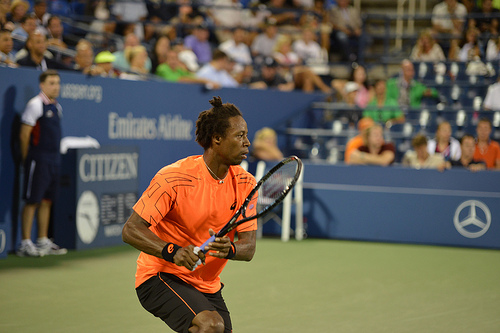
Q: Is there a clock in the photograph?
A: Yes, there is a clock.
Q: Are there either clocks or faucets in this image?
A: Yes, there is a clock.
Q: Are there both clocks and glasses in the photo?
A: No, there is a clock but no glasses.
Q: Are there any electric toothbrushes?
A: No, there are no electric toothbrushes.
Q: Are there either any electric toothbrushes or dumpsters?
A: No, there are no electric toothbrushes or dumpsters.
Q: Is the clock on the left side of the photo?
A: Yes, the clock is on the left of the image.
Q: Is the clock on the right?
A: No, the clock is on the left of the image.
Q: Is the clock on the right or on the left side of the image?
A: The clock is on the left of the image.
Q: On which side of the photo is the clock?
A: The clock is on the left of the image.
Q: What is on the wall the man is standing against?
A: The clock is on the wall.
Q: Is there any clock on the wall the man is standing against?
A: Yes, there is a clock on the wall.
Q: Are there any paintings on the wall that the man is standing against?
A: No, there is a clock on the wall.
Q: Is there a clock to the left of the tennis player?
A: Yes, there is a clock to the left of the player.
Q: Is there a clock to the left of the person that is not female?
A: Yes, there is a clock to the left of the player.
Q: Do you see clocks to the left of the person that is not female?
A: Yes, there is a clock to the left of the player.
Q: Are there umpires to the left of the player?
A: No, there is a clock to the left of the player.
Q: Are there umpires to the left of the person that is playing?
A: No, there is a clock to the left of the player.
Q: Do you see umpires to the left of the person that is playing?
A: No, there is a clock to the left of the player.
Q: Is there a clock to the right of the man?
A: Yes, there is a clock to the right of the man.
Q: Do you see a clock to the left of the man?
A: No, the clock is to the right of the man.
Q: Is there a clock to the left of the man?
A: No, the clock is to the right of the man.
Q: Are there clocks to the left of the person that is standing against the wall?
A: No, the clock is to the right of the man.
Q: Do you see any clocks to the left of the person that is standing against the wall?
A: No, the clock is to the right of the man.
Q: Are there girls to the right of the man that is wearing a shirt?
A: No, there is a clock to the right of the man.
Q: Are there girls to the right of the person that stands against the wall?
A: No, there is a clock to the right of the man.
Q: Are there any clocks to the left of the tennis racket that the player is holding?
A: Yes, there is a clock to the left of the racket.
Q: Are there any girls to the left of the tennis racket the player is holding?
A: No, there is a clock to the left of the tennis racket.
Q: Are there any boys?
A: No, there are no boys.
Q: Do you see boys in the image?
A: No, there are no boys.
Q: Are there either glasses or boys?
A: No, there are no boys or glasses.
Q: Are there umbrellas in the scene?
A: No, there are no umbrellas.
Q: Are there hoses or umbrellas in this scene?
A: No, there are no umbrellas or hoses.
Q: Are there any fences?
A: No, there are no fences.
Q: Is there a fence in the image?
A: No, there are no fences.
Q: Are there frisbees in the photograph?
A: No, there are no frisbees.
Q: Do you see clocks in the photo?
A: Yes, there is a clock.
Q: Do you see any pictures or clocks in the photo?
A: Yes, there is a clock.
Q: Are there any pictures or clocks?
A: Yes, there is a clock.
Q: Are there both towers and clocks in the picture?
A: No, there is a clock but no towers.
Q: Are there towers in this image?
A: No, there are no towers.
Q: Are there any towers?
A: No, there are no towers.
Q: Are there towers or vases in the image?
A: No, there are no towers or vases.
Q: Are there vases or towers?
A: No, there are no towers or vases.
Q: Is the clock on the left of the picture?
A: Yes, the clock is on the left of the image.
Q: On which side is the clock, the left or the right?
A: The clock is on the left of the image.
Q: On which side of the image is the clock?
A: The clock is on the left of the image.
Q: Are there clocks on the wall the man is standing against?
A: Yes, there is a clock on the wall.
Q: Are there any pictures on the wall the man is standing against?
A: No, there is a clock on the wall.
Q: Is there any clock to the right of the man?
A: Yes, there is a clock to the right of the man.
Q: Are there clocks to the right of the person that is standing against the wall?
A: Yes, there is a clock to the right of the man.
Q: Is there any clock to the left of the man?
A: No, the clock is to the right of the man.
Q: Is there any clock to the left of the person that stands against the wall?
A: No, the clock is to the right of the man.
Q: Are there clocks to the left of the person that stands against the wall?
A: No, the clock is to the right of the man.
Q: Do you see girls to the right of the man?
A: No, there is a clock to the right of the man.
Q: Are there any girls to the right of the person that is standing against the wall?
A: No, there is a clock to the right of the man.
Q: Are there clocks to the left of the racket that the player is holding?
A: Yes, there is a clock to the left of the tennis racket.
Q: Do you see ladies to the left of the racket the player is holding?
A: No, there is a clock to the left of the racket.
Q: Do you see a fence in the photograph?
A: No, there are no fences.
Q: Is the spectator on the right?
A: Yes, the spectator is on the right of the image.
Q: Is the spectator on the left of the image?
A: No, the spectator is on the right of the image.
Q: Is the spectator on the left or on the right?
A: The spectator is on the right of the image.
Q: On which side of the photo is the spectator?
A: The spectator is on the right of the image.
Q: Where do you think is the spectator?
A: The spectator is at the match.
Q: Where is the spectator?
A: The spectator is at the match.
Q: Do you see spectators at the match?
A: Yes, there is a spectator at the match.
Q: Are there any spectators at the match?
A: Yes, there is a spectator at the match.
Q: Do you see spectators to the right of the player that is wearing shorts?
A: Yes, there is a spectator to the right of the player.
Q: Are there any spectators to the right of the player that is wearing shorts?
A: Yes, there is a spectator to the right of the player.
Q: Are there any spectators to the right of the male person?
A: Yes, there is a spectator to the right of the player.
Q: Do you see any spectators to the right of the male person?
A: Yes, there is a spectator to the right of the player.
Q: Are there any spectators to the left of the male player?
A: No, the spectator is to the right of the player.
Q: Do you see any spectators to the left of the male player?
A: No, the spectator is to the right of the player.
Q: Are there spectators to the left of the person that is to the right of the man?
A: No, the spectator is to the right of the player.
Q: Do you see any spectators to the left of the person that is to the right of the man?
A: No, the spectator is to the right of the player.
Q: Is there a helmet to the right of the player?
A: No, there is a spectator to the right of the player.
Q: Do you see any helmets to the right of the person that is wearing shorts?
A: No, there is a spectator to the right of the player.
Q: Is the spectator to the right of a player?
A: Yes, the spectator is to the right of a player.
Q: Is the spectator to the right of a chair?
A: No, the spectator is to the right of a player.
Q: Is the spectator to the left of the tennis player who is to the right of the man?
A: No, the spectator is to the right of the player.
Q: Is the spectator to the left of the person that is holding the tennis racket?
A: No, the spectator is to the right of the player.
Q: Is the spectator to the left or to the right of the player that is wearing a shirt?
A: The spectator is to the right of the player.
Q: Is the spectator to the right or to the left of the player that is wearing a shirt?
A: The spectator is to the right of the player.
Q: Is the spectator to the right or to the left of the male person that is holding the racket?
A: The spectator is to the right of the player.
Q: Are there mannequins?
A: No, there are no mannequins.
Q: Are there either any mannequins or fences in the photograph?
A: No, there are no mannequins or fences.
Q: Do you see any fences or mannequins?
A: No, there are no mannequins or fences.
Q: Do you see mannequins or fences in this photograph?
A: No, there are no mannequins or fences.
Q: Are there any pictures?
A: No, there are no pictures.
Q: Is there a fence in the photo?
A: No, there are no fences.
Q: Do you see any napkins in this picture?
A: No, there are no napkins.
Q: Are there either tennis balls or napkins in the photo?
A: No, there are no napkins or tennis balls.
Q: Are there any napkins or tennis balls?
A: No, there are no napkins or tennis balls.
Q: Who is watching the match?
A: The audience is watching the match.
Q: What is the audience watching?
A: The audience is watching the match.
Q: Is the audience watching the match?
A: Yes, the audience is watching the match.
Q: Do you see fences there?
A: No, there are no fences.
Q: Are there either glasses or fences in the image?
A: No, there are no fences or glasses.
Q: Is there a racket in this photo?
A: Yes, there is a racket.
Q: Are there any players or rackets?
A: Yes, there is a racket.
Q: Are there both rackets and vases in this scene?
A: No, there is a racket but no vases.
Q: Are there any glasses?
A: No, there are no glasses.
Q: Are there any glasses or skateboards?
A: No, there are no glasses or skateboards.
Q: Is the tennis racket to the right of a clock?
A: Yes, the tennis racket is to the right of a clock.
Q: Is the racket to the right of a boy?
A: No, the racket is to the right of a clock.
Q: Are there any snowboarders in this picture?
A: No, there are no snowboarders.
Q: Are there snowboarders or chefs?
A: No, there are no snowboarders or chefs.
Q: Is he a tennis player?
A: Yes, this is a tennis player.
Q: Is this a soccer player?
A: No, this is a tennis player.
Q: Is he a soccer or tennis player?
A: This is a tennis player.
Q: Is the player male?
A: Yes, the player is male.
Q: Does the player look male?
A: Yes, the player is male.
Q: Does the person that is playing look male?
A: Yes, the player is male.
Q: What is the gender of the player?
A: The player is male.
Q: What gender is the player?
A: The player is male.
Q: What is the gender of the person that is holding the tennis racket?
A: The player is male.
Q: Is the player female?
A: No, the player is male.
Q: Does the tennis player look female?
A: No, the player is male.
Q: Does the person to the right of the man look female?
A: No, the player is male.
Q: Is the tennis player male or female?
A: The player is male.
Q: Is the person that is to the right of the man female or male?
A: The player is male.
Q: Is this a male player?
A: Yes, this is a male player.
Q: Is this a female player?
A: No, this is a male player.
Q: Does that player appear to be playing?
A: Yes, the player is playing.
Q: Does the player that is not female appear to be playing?
A: Yes, the player is playing.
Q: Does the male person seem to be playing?
A: Yes, the player is playing.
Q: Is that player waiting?
A: No, the player is playing.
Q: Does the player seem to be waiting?
A: No, the player is playing.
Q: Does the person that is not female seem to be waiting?
A: No, the player is playing.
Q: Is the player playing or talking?
A: The player is playing.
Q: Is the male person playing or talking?
A: The player is playing.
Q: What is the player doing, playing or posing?
A: The player is playing.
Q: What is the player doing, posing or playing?
A: The player is playing.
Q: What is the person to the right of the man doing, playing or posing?
A: The player is playing.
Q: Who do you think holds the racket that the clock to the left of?
A: The player holds the racket.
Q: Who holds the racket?
A: The player holds the racket.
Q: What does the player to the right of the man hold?
A: The player holds the racket.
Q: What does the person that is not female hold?
A: The player holds the racket.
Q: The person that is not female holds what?
A: The player holds the racket.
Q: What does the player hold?
A: The player holds the racket.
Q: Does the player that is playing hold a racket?
A: Yes, the player holds a racket.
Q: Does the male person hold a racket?
A: Yes, the player holds a racket.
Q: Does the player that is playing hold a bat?
A: No, the player holds a racket.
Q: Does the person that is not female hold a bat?
A: No, the player holds a racket.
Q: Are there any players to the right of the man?
A: Yes, there is a player to the right of the man.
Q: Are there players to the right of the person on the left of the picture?
A: Yes, there is a player to the right of the man.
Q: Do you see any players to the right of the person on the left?
A: Yes, there is a player to the right of the man.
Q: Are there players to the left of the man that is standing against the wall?
A: No, the player is to the right of the man.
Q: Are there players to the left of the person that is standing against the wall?
A: No, the player is to the right of the man.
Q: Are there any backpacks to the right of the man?
A: No, there is a player to the right of the man.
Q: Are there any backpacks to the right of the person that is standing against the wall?
A: No, there is a player to the right of the man.